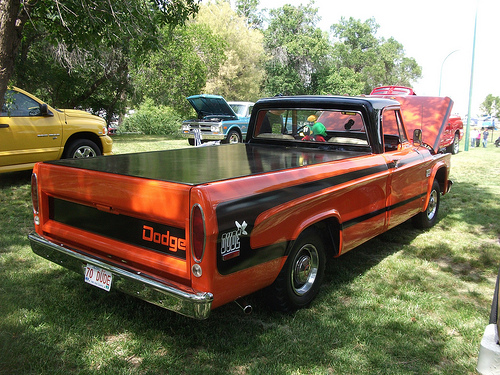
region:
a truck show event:
[0, 0, 497, 374]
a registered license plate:
[82, 262, 112, 289]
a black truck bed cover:
[41, 140, 371, 180]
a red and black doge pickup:
[30, 95, 452, 317]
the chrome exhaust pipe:
[233, 298, 253, 315]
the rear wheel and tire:
[276, 231, 326, 310]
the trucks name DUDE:
[218, 219, 248, 261]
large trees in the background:
[1, 1, 369, 94]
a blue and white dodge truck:
[181, 93, 249, 143]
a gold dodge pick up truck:
[1, 83, 111, 168]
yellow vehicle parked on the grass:
[0, 83, 121, 184]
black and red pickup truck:
[26, 76, 470, 326]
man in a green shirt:
[289, 109, 335, 146]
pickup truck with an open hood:
[151, 79, 295, 141]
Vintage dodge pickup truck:
[26, 78, 488, 338]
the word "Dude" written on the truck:
[202, 209, 259, 269]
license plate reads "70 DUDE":
[71, 252, 128, 304]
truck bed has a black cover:
[29, 121, 384, 213]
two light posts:
[408, 10, 487, 163]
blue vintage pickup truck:
[170, 70, 313, 160]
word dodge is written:
[159, 231, 175, 256]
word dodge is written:
[149, 231, 160, 238]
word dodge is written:
[168, 235, 180, 260]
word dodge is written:
[155, 231, 165, 246]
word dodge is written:
[162, 236, 172, 248]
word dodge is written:
[152, 223, 165, 240]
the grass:
[309, 324, 359, 370]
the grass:
[341, 321, 389, 373]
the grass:
[359, 325, 391, 358]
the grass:
[374, 319, 396, 367]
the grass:
[336, 351, 353, 359]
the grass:
[391, 330, 414, 365]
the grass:
[340, 289, 396, 368]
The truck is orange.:
[32, 72, 467, 320]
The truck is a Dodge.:
[16, 77, 468, 336]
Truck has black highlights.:
[24, 87, 470, 321]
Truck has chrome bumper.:
[16, 80, 462, 335]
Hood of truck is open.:
[25, 75, 469, 323]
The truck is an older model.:
[28, 86, 475, 330]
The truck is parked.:
[26, 83, 498, 370]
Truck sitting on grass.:
[23, 74, 498, 326]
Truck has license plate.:
[17, 61, 466, 337]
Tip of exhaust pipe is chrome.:
[23, 88, 465, 342]